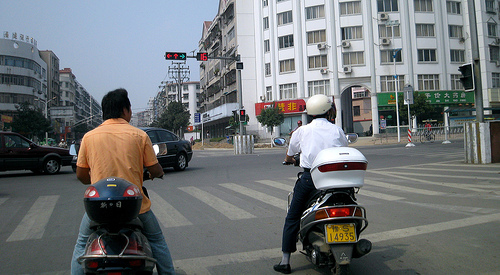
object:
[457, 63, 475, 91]
light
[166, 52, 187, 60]
light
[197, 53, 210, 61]
light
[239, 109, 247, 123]
light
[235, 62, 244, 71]
light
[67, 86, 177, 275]
man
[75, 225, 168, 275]
moped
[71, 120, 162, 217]
shirt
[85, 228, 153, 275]
back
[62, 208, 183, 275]
jeans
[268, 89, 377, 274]
person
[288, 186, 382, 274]
moped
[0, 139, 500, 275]
road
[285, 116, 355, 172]
shirt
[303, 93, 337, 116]
helmet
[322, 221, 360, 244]
plate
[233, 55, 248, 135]
pole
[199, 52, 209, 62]
number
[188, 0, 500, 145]
building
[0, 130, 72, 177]
car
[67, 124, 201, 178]
car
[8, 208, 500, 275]
lines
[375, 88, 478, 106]
sign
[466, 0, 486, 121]
pole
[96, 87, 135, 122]
hair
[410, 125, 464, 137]
rack